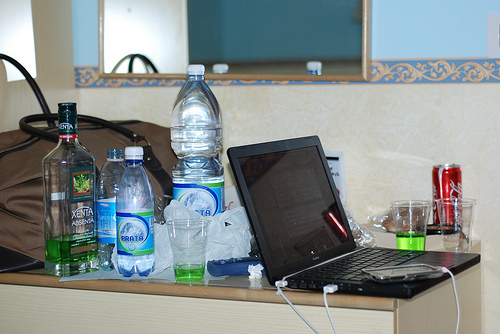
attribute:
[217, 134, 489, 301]
laptop — open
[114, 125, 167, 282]
bottle — uncapped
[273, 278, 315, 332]
cord — white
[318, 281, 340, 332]
cord — white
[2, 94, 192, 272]
bag — brown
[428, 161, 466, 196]
soda can — red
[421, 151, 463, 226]
can — coke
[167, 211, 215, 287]
cup — plastic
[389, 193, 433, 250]
cup — plastic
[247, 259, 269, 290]
paper — crumpled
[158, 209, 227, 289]
glass — green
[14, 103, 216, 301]
bag — brown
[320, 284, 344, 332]
cord — white